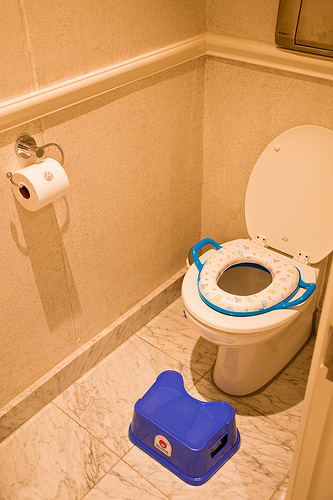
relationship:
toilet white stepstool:
[171, 161, 296, 387] [128, 370, 240, 488]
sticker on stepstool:
[146, 428, 181, 460] [130, 397, 240, 461]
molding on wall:
[62, 70, 165, 83] [0, 22, 206, 402]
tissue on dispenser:
[9, 158, 70, 212] [16, 128, 76, 187]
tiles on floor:
[2, 265, 331, 497] [37, 365, 159, 466]